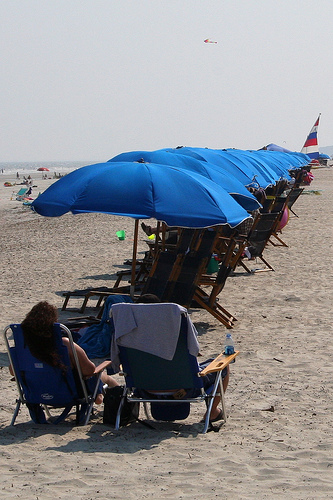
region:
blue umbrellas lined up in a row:
[29, 143, 312, 229]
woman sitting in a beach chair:
[19, 298, 118, 405]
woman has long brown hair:
[19, 299, 67, 378]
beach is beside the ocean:
[0, 160, 93, 179]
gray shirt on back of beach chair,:
[107, 302, 199, 373]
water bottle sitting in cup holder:
[224, 332, 233, 353]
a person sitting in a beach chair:
[2, 303, 106, 432]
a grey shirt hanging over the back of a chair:
[110, 297, 196, 365]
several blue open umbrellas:
[40, 144, 313, 237]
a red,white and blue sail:
[299, 111, 324, 166]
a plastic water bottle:
[220, 329, 237, 352]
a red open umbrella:
[36, 164, 50, 173]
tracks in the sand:
[232, 417, 310, 495]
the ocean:
[0, 156, 78, 176]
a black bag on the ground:
[100, 381, 137, 429]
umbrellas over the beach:
[33, 130, 313, 265]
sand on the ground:
[248, 393, 313, 462]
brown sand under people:
[221, 407, 309, 465]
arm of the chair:
[193, 338, 250, 388]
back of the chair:
[95, 290, 214, 400]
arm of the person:
[61, 331, 103, 388]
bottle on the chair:
[212, 324, 244, 370]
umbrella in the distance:
[24, 152, 70, 188]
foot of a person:
[132, 215, 159, 242]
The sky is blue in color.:
[14, 9, 125, 80]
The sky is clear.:
[8, 13, 122, 107]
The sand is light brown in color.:
[164, 459, 303, 494]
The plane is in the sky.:
[202, 36, 218, 46]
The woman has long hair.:
[13, 299, 75, 376]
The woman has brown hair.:
[20, 301, 71, 376]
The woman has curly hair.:
[20, 300, 70, 374]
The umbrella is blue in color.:
[29, 160, 253, 228]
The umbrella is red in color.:
[37, 164, 48, 173]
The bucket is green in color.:
[115, 229, 126, 241]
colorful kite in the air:
[202, 36, 217, 46]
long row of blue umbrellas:
[31, 146, 328, 227]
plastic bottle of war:
[224, 334, 236, 363]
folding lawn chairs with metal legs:
[2, 302, 229, 433]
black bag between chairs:
[104, 384, 140, 427]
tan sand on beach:
[0, 161, 331, 498]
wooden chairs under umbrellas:
[54, 159, 310, 329]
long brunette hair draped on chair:
[22, 299, 61, 354]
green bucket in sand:
[114, 229, 125, 239]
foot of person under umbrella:
[140, 218, 167, 234]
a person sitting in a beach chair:
[4, 299, 105, 428]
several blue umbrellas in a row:
[50, 152, 309, 238]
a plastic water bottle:
[223, 333, 234, 354]